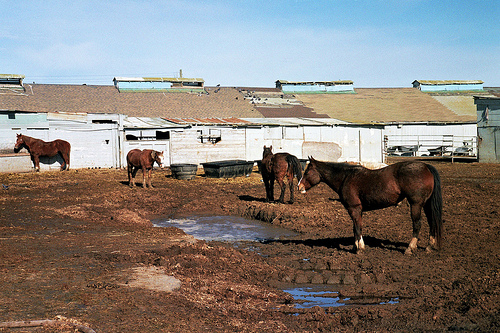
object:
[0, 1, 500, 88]
sky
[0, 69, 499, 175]
barn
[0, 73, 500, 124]
roof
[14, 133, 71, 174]
horses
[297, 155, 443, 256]
horse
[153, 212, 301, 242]
water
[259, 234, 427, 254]
shadow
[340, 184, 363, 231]
legs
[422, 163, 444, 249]
tail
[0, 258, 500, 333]
ground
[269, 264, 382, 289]
mud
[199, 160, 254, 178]
container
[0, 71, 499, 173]
structures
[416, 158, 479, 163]
shadow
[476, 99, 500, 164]
wall